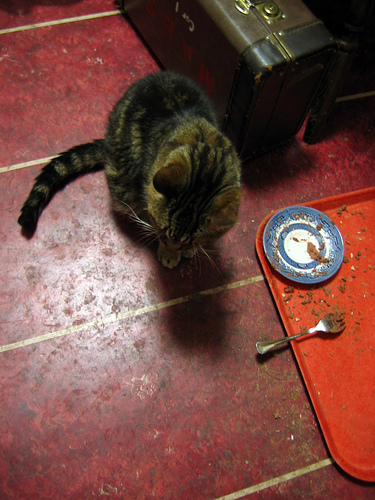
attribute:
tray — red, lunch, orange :
[255, 188, 373, 483]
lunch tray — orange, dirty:
[252, 182, 373, 487]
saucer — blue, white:
[286, 202, 337, 285]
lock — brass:
[234, 0, 283, 23]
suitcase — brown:
[117, 0, 335, 158]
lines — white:
[3, 7, 276, 496]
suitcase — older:
[109, 0, 338, 143]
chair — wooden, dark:
[302, 0, 372, 145]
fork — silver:
[269, 301, 364, 374]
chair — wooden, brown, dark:
[245, 3, 368, 149]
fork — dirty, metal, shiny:
[255, 310, 346, 358]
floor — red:
[1, 0, 373, 496]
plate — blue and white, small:
[261, 203, 347, 287]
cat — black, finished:
[13, 68, 243, 269]